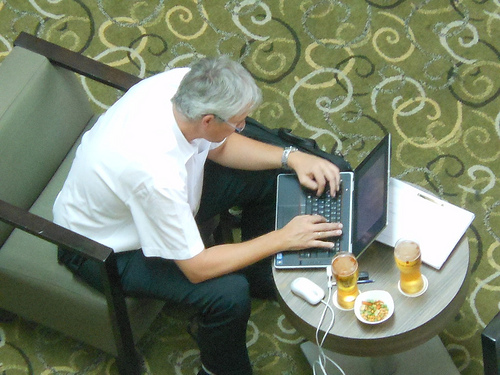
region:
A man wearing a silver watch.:
[263, 141, 318, 174]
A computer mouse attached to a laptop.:
[266, 261, 348, 341]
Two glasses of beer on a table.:
[313, 251, 440, 283]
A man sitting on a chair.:
[19, 83, 266, 326]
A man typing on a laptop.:
[280, 155, 346, 287]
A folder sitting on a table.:
[399, 170, 463, 259]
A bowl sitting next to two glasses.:
[329, 287, 403, 336]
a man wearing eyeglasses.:
[223, 110, 251, 142]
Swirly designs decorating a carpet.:
[278, 12, 411, 103]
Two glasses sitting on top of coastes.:
[339, 235, 428, 301]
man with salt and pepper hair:
[179, 46, 251, 126]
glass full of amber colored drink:
[392, 238, 427, 302]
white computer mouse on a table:
[290, 272, 326, 310]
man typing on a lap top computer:
[268, 143, 387, 260]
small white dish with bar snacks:
[357, 291, 393, 322]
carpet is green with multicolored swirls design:
[307, 30, 499, 154]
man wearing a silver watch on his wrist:
[278, 141, 297, 174]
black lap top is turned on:
[275, 168, 400, 257]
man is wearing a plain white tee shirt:
[89, 80, 226, 250]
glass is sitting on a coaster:
[391, 244, 430, 306]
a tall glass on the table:
[393, 238, 423, 296]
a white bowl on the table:
[355, 288, 395, 323]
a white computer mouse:
[290, 277, 326, 304]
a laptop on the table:
[276, 131, 386, 270]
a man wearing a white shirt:
[51, 58, 344, 373]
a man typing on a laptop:
[53, 54, 340, 373]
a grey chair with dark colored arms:
[5, 31, 163, 371]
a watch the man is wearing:
[280, 145, 297, 172]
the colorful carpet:
[290, 14, 496, 121]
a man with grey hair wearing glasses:
[52, 54, 342, 372]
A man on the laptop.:
[131, 70, 408, 279]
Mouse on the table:
[287, 258, 326, 310]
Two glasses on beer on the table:
[324, 242, 438, 298]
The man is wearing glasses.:
[222, 100, 253, 134]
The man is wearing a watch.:
[269, 138, 309, 163]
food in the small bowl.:
[353, 285, 408, 337]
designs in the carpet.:
[351, 67, 460, 146]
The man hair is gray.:
[181, 84, 248, 111]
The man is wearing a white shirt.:
[83, 107, 176, 204]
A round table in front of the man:
[269, 193, 487, 356]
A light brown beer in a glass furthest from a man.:
[393, 236, 426, 296]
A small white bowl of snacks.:
[353, 290, 395, 324]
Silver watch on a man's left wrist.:
[277, 142, 298, 166]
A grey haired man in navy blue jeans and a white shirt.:
[51, 55, 342, 373]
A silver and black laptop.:
[273, 133, 393, 267]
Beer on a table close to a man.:
[327, 252, 360, 309]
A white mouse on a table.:
[288, 278, 326, 306]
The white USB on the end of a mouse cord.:
[325, 265, 334, 277]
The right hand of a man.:
[289, 150, 341, 197]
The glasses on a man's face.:
[201, 109, 247, 134]